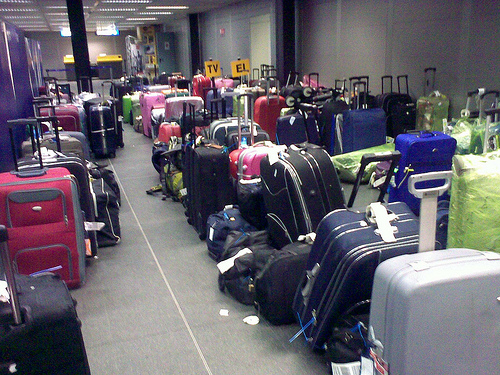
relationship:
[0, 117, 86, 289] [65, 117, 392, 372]
luggage on floor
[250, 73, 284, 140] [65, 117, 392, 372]
suitcase on floor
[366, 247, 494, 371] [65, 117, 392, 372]
suitcase on floor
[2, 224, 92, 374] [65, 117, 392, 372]
suitcase on floor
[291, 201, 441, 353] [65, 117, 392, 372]
blue suitcase on floor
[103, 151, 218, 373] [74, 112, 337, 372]
line in middle of floor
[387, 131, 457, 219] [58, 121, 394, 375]
blue suitcase on floor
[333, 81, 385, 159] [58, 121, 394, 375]
blue suitcase on floor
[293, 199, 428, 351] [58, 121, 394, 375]
blue suitcase on floor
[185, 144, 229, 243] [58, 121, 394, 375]
blue suitcase on floor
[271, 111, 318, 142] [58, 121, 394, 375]
blue suitcase on floor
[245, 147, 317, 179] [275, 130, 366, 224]
handle on suitcase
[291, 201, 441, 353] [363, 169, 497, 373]
blue suitcase next to suitcase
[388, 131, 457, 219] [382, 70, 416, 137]
blue suitcase next to suitcase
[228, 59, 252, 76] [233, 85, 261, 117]
sign above suitcase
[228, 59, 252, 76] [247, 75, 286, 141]
sign above suitcase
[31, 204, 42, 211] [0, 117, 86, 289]
button on luggage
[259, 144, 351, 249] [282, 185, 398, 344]
suitcase next to suitcase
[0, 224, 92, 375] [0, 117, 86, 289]
suitcase next to luggage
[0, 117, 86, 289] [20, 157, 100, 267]
luggage next to suitcase